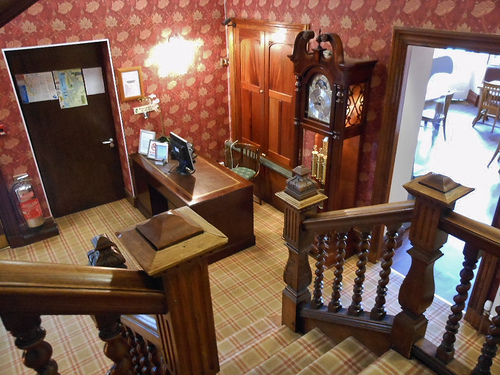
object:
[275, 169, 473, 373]
stair rail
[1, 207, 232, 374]
stair rail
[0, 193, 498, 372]
rug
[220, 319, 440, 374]
stairs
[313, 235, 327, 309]
railing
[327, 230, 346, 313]
railing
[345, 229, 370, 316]
railing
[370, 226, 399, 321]
railing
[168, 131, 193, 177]
monitor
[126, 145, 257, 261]
desk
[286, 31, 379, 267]
grandfather clock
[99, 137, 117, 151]
door knob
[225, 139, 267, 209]
chair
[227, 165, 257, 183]
cushion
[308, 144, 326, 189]
chimes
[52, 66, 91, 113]
map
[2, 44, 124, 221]
door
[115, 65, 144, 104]
frame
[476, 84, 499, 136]
chair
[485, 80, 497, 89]
table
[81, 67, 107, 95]
paper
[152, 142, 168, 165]
frame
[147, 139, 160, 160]
frame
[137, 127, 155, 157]
frame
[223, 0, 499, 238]
wall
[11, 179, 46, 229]
fire extinguisher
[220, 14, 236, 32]
security camera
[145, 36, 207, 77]
light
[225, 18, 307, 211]
doors